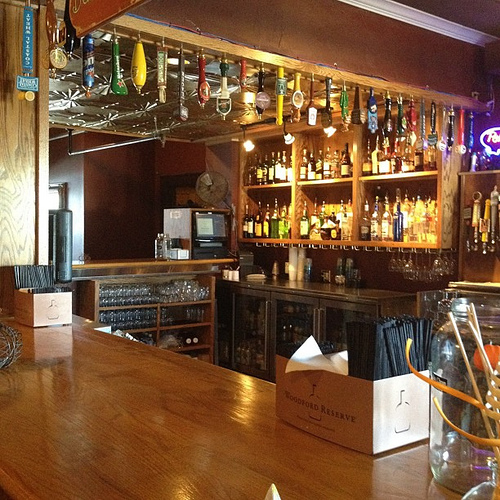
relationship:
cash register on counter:
[185, 204, 235, 250] [80, 229, 222, 279]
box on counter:
[267, 319, 440, 457] [3, 295, 498, 499]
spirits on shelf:
[363, 184, 443, 244] [236, 109, 455, 240]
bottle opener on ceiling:
[176, 41, 190, 124] [348, 35, 459, 75]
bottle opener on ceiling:
[154, 35, 168, 105] [348, 35, 459, 75]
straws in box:
[324, 291, 424, 398] [249, 361, 440, 461]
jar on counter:
[421, 287, 498, 494] [79, 391, 231, 477]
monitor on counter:
[184, 212, 233, 252] [93, 376, 205, 467]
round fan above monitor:
[197, 170, 227, 204] [193, 210, 230, 239]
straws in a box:
[426, 320, 434, 362] [274, 352, 429, 454]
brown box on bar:
[10, 278, 92, 333] [3, 335, 306, 426]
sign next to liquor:
[453, 116, 498, 154] [144, 34, 264, 129]